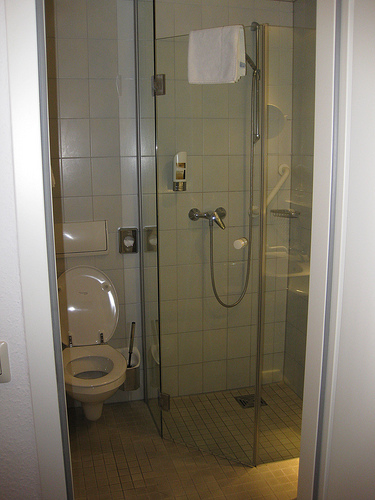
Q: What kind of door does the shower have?
A: Glass.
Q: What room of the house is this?
A: Bathroom.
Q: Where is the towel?
A: Hanging on the shower door.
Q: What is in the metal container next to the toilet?
A: Toilet brush.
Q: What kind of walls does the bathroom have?
A: Tile.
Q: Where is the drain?
A: Corner of the shower.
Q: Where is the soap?
A: On the wall.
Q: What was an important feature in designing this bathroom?
A: Space.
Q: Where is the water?
A: In the toilet bowl.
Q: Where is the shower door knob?
A: Right side of the door.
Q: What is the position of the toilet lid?
A: Up.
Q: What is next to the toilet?
A: A toilet brush?.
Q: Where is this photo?
A: In a bathroom.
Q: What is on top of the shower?
A: A towel.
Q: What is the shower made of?
A: Glass.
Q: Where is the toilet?
A: Close to the shower.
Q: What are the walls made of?
A: Tile.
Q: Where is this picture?
A: A bathroom.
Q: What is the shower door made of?
A: Glass.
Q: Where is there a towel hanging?
A: Shower door.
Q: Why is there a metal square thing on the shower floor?
A: Drain water.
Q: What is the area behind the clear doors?
A: Shower.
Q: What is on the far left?
A: Toilet.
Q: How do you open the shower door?
A: White knob.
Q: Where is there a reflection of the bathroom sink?
A: Right side of shower.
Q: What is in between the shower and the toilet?
A: Toilet cleaning brush.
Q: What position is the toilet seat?
A: Up.